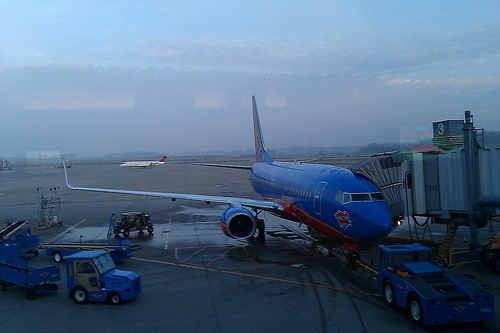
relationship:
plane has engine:
[63, 93, 394, 259] [222, 206, 256, 239]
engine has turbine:
[222, 206, 256, 239] [230, 216, 251, 237]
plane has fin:
[63, 93, 394, 259] [250, 95, 274, 162]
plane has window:
[63, 93, 394, 259] [351, 192, 370, 200]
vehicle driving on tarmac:
[69, 250, 140, 303] [6, 156, 499, 329]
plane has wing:
[63, 93, 394, 259] [60, 156, 282, 212]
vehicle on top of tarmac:
[69, 250, 140, 303] [6, 156, 499, 329]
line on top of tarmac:
[132, 255, 378, 295] [6, 156, 499, 329]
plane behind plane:
[121, 154, 167, 167] [63, 93, 394, 259]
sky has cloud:
[1, 0, 499, 160] [382, 76, 485, 85]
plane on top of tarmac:
[63, 93, 394, 259] [6, 156, 499, 329]